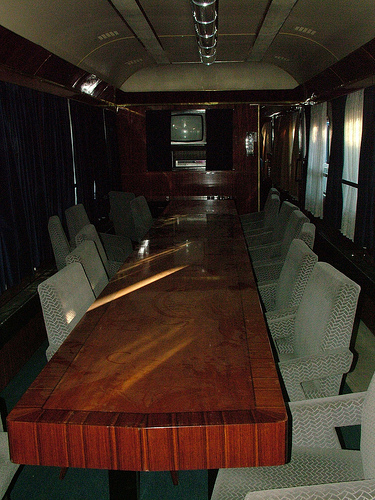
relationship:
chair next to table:
[210, 371, 374, 499] [8, 193, 286, 469]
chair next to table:
[266, 261, 365, 396] [8, 193, 286, 469]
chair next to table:
[258, 236, 318, 314] [8, 193, 286, 469]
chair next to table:
[38, 261, 97, 363] [8, 193, 286, 469]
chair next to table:
[65, 240, 109, 299] [8, 193, 286, 469]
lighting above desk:
[190, 0, 217, 68] [22, 183, 296, 473]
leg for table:
[108, 468, 139, 498] [8, 193, 286, 469]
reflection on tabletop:
[64, 236, 194, 400] [9, 190, 288, 423]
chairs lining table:
[251, 237, 367, 381] [11, 236, 295, 464]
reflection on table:
[76, 263, 195, 306] [69, 166, 280, 330]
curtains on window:
[339, 86, 366, 242] [333, 78, 370, 263]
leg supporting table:
[109, 472, 139, 497] [8, 193, 286, 469]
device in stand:
[172, 157, 208, 167] [133, 106, 259, 198]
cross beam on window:
[338, 94, 365, 250] [342, 178, 360, 188]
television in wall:
[157, 101, 217, 156] [129, 93, 257, 204]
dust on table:
[121, 333, 155, 366] [8, 193, 286, 469]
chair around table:
[266, 261, 365, 396] [5, 200, 288, 490]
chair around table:
[255, 235, 317, 322] [5, 200, 288, 490]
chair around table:
[245, 197, 299, 250] [5, 200, 288, 490]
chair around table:
[38, 261, 97, 363] [5, 200, 288, 490]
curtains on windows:
[306, 107, 325, 217] [306, 101, 369, 232]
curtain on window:
[0, 78, 70, 301] [1, 69, 73, 306]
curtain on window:
[0, 78, 148, 311] [66, 94, 108, 222]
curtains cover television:
[146, 110, 171, 168] [171, 110, 204, 145]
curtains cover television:
[203, 107, 234, 170] [171, 110, 204, 145]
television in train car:
[169, 108, 208, 146] [2, 0, 371, 500]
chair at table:
[263, 261, 360, 401] [98, 198, 272, 405]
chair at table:
[38, 261, 97, 363] [98, 198, 272, 405]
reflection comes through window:
[64, 236, 194, 400] [335, 85, 367, 241]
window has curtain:
[336, 92, 369, 251] [339, 90, 361, 242]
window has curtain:
[301, 98, 329, 216] [304, 102, 331, 218]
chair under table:
[30, 261, 100, 359] [8, 193, 286, 469]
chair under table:
[65, 240, 109, 299] [8, 193, 286, 469]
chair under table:
[71, 221, 127, 282] [8, 193, 286, 469]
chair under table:
[127, 191, 157, 247] [8, 193, 286, 469]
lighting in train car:
[190, 0, 218, 70] [2, 0, 371, 500]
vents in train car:
[294, 24, 318, 37] [2, 0, 371, 500]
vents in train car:
[275, 52, 291, 61] [2, 0, 371, 500]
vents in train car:
[97, 28, 120, 40] [2, 0, 371, 500]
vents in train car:
[125, 54, 143, 66] [2, 0, 371, 500]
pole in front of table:
[246, 98, 267, 218] [132, 195, 258, 328]